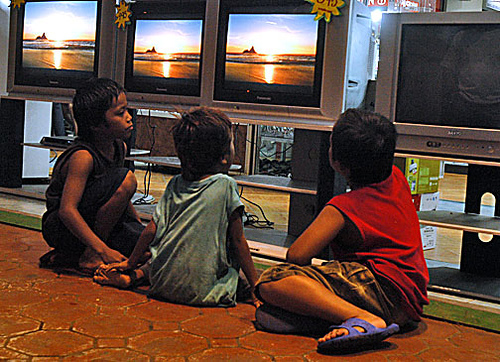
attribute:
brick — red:
[129, 329, 209, 354]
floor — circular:
[1, 222, 498, 359]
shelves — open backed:
[1, 94, 498, 307]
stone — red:
[451, 319, 497, 359]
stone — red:
[415, 310, 461, 342]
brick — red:
[301, 346, 399, 361]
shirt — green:
[154, 172, 244, 305]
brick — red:
[7, 240, 30, 249]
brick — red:
[158, 310, 225, 342]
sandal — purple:
[311, 313, 403, 354]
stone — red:
[24, 301, 121, 351]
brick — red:
[71, 311, 154, 339]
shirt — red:
[308, 175, 454, 295]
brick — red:
[239, 329, 317, 355]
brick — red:
[78, 346, 151, 358]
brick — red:
[183, 346, 272, 360]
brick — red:
[177, 311, 254, 336]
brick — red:
[23, 292, 100, 319]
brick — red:
[447, 328, 499, 352]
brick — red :
[3, 290, 223, 360]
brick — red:
[123, 322, 216, 356]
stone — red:
[2, 200, 497, 357]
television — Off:
[373, 11, 498, 159]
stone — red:
[121, 321, 222, 361]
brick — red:
[24, 290, 105, 326]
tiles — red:
[6, 329, 96, 360]